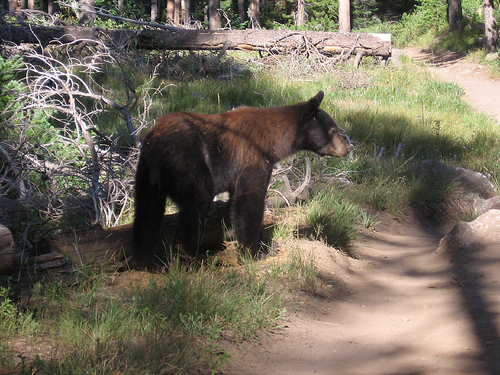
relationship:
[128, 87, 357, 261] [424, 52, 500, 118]
bear near road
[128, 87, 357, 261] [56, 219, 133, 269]
bear standing next to log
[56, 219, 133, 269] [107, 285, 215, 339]
log laying on top of ground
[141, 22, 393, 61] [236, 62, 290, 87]
tree trunk laying on grass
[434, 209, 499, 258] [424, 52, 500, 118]
stone on top of road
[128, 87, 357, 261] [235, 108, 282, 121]
bear has fur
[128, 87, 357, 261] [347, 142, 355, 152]
bear has snout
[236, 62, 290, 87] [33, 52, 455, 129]
grass in field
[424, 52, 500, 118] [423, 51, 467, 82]
road made of dirt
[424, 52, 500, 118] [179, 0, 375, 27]
road leads into woods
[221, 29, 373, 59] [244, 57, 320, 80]
tree on top of ground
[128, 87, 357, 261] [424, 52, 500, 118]
bear standing next to road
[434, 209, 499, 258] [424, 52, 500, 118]
stone next to road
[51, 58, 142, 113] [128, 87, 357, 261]
branches are beside bear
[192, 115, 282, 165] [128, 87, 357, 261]
shadow on bear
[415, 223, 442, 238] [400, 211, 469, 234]
dirt in groove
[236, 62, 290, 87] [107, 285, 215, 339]
grass on top of ground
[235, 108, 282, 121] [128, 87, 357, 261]
fur on bear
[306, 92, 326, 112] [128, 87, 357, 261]
ear on bear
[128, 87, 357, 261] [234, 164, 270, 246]
bear has leg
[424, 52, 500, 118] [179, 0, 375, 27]
road leading in to woods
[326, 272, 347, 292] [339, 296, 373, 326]
stones in dirt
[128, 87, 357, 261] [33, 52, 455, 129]
bear in field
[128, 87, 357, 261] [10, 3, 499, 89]
bear in nature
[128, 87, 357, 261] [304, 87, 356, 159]
bear has head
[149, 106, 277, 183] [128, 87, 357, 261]
body of bear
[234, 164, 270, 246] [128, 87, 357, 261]
leg of bear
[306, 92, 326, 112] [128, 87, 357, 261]
ear of bear